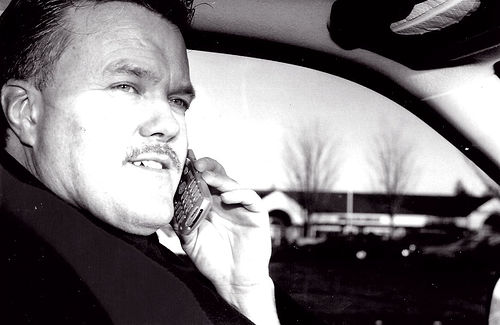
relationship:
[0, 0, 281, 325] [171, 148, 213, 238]
man on cellphone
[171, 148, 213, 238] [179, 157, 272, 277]
cellphone in hand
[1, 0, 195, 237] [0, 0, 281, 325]
head of man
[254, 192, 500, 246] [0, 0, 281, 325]
shopping mall behind man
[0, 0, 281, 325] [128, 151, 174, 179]
man has mouth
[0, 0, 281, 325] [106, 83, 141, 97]
man has eye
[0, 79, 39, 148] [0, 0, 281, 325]
ear on man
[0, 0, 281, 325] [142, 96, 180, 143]
man has nose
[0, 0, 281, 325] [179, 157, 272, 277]
man has hand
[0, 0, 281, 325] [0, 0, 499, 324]
man in car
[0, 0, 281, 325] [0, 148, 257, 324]
man wearing jacket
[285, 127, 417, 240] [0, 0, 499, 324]
trees outside car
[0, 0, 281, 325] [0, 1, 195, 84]
man with hair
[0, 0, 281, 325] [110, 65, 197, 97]
man has eyebrows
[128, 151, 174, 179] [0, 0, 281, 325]
mouth on man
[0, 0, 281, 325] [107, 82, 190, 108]
man has eyes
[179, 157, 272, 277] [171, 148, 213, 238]
hand holding cellphone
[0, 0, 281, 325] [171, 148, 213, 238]
man holding cellphone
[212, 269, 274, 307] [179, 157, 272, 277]
wrist under hand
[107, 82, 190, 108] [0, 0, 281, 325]
eyes on man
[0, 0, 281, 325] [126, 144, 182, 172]
man has moustache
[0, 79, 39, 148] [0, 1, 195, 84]
ear under hair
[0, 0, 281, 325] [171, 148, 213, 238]
man talking on cellphone